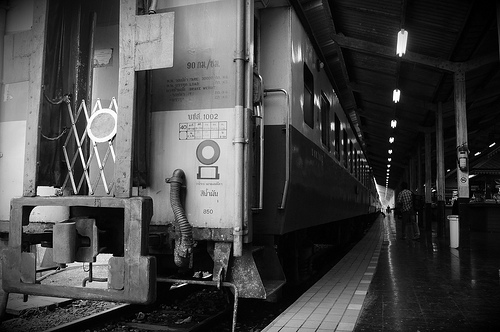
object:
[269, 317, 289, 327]
tile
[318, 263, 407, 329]
surface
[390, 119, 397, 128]
light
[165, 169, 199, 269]
coil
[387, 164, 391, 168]
lights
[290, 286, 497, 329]
floor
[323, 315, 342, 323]
tile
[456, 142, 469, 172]
fire exstinguisher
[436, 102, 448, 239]
post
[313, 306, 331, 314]
tile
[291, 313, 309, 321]
tile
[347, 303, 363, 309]
tile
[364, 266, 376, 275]
tile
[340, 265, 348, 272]
tile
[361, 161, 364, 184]
window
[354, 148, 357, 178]
window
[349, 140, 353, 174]
window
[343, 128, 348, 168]
window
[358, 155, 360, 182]
window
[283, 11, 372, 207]
wall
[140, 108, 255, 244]
electrical system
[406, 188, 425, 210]
backpack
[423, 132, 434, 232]
post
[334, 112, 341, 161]
window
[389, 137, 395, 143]
light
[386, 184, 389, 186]
lights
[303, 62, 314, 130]
window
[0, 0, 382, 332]
train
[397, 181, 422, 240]
man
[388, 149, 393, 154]
light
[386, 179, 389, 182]
light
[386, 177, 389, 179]
light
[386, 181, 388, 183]
light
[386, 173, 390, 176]
light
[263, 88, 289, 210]
rail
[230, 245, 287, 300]
step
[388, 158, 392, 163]
light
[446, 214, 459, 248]
trash can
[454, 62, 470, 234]
pole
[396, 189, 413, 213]
plaid shirt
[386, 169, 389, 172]
lights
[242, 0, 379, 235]
side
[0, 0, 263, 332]
back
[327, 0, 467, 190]
ceiling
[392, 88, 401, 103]
light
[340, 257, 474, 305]
hallway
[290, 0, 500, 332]
building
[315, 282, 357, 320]
color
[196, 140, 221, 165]
circle